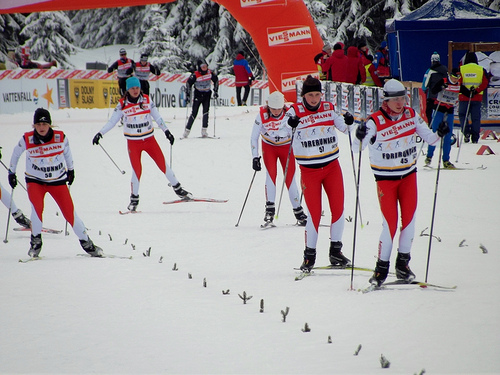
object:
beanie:
[299, 74, 322, 97]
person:
[350, 72, 457, 289]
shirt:
[276, 102, 356, 165]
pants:
[300, 157, 345, 249]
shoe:
[298, 247, 317, 276]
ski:
[161, 197, 230, 207]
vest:
[284, 101, 339, 169]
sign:
[261, 22, 311, 48]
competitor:
[9, 107, 103, 256]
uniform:
[7, 128, 106, 259]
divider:
[202, 277, 208, 287]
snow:
[0, 102, 499, 374]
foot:
[257, 200, 278, 223]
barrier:
[4, 59, 134, 112]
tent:
[383, 2, 497, 122]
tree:
[137, 3, 271, 82]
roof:
[395, 6, 486, 42]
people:
[274, 74, 364, 273]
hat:
[382, 77, 408, 100]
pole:
[95, 138, 128, 178]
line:
[126, 226, 363, 356]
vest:
[460, 64, 483, 102]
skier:
[176, 56, 221, 141]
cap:
[126, 73, 143, 89]